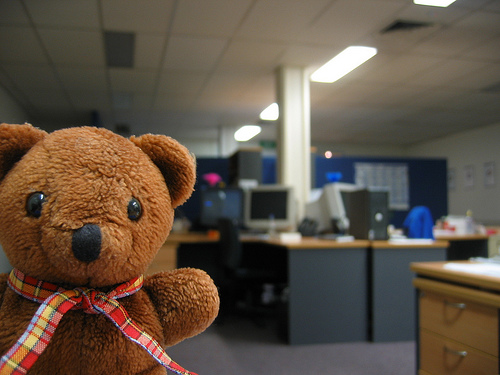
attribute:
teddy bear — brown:
[1, 124, 220, 375]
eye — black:
[25, 191, 45, 217]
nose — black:
[71, 224, 101, 263]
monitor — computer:
[243, 187, 292, 228]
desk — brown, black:
[242, 232, 370, 345]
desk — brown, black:
[370, 239, 449, 342]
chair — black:
[217, 217, 278, 334]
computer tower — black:
[348, 191, 388, 241]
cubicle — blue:
[263, 157, 447, 229]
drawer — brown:
[419, 289, 500, 355]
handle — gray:
[444, 300, 465, 308]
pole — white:
[276, 65, 310, 222]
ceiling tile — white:
[161, 32, 230, 75]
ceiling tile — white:
[35, 26, 107, 69]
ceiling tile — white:
[409, 57, 491, 91]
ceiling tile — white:
[156, 68, 208, 97]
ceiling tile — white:
[57, 63, 109, 103]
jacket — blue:
[401, 206, 433, 238]